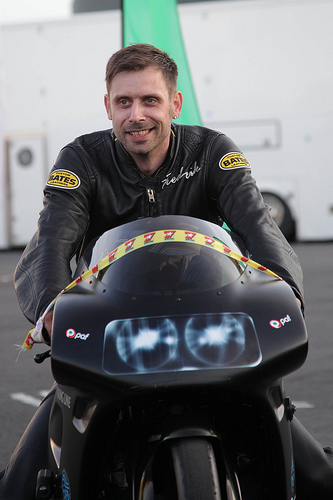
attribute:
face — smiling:
[97, 49, 193, 168]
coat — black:
[41, 133, 296, 282]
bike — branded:
[34, 199, 264, 496]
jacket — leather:
[30, 123, 256, 261]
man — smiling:
[77, 51, 198, 184]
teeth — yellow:
[122, 124, 168, 143]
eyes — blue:
[103, 89, 168, 110]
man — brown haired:
[91, 40, 199, 148]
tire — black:
[155, 432, 236, 495]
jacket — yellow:
[41, 149, 131, 218]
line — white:
[6, 383, 47, 410]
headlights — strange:
[103, 308, 267, 379]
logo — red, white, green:
[60, 322, 76, 340]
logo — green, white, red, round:
[69, 328, 91, 343]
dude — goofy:
[80, 36, 183, 173]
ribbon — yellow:
[92, 228, 241, 266]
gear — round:
[26, 344, 63, 373]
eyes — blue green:
[108, 90, 164, 110]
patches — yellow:
[209, 144, 258, 183]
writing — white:
[158, 161, 205, 192]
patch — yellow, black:
[44, 165, 82, 192]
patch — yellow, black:
[213, 150, 253, 172]